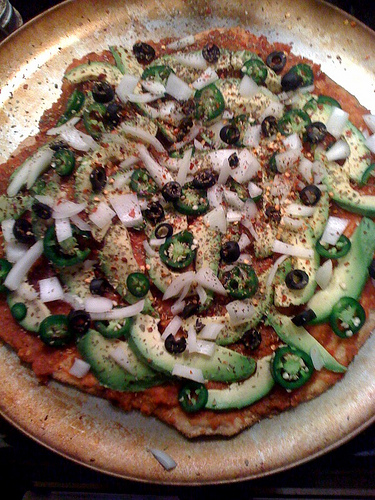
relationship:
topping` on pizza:
[126, 103, 315, 363] [18, 17, 321, 480]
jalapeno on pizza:
[253, 340, 327, 396] [18, 17, 321, 480]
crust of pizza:
[26, 406, 128, 498] [18, 17, 321, 480]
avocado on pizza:
[195, 345, 294, 419] [18, 17, 321, 480]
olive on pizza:
[290, 267, 302, 285] [18, 17, 321, 480]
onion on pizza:
[299, 254, 353, 304] [18, 17, 321, 480]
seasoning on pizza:
[148, 137, 213, 217] [18, 17, 321, 480]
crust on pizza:
[26, 406, 128, 498] [18, 17, 321, 480]